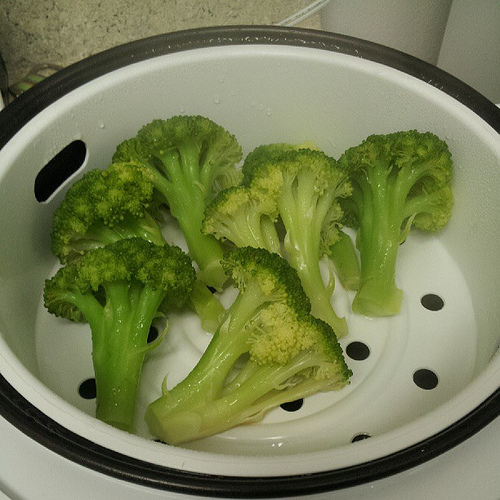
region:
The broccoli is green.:
[332, 120, 455, 326]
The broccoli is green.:
[244, 143, 358, 275]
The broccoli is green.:
[195, 173, 290, 260]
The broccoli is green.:
[106, 108, 251, 254]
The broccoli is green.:
[43, 160, 176, 270]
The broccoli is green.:
[38, 228, 200, 438]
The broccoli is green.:
[146, 234, 358, 469]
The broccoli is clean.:
[146, 235, 359, 458]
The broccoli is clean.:
[36, 225, 199, 432]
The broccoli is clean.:
[331, 113, 461, 334]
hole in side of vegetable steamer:
[36, 125, 90, 208]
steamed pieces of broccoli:
[60, 118, 447, 440]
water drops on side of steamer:
[74, 98, 109, 140]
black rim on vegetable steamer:
[15, 408, 97, 480]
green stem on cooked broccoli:
[350, 209, 407, 317]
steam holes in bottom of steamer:
[335, 277, 471, 407]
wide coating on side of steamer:
[240, 66, 352, 138]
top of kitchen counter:
[7, 0, 92, 45]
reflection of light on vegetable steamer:
[259, 427, 292, 454]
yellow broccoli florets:
[246, 159, 293, 219]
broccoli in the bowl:
[357, 142, 431, 320]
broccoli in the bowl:
[219, 303, 298, 411]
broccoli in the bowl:
[55, 260, 151, 399]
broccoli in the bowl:
[45, 168, 153, 227]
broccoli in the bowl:
[152, 103, 215, 194]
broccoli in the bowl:
[189, 183, 281, 235]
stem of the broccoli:
[136, 380, 198, 444]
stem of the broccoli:
[96, 384, 150, 421]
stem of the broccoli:
[362, 269, 399, 320]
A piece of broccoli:
[47, 237, 204, 417]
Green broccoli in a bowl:
[49, 235, 195, 422]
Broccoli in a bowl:
[15, 35, 482, 472]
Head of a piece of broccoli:
[46, 239, 206, 326]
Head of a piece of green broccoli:
[54, 241, 195, 331]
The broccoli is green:
[35, 60, 436, 463]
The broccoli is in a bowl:
[33, 55, 461, 478]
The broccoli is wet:
[49, 28, 428, 480]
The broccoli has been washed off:
[40, 55, 449, 462]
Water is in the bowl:
[78, 84, 130, 131]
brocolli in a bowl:
[29, 22, 464, 469]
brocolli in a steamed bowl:
[84, 131, 405, 486]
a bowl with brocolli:
[72, 138, 499, 493]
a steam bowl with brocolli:
[50, 125, 437, 488]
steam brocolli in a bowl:
[85, 90, 498, 495]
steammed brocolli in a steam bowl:
[75, 100, 497, 416]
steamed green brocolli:
[36, 110, 468, 496]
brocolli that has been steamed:
[77, 110, 485, 411]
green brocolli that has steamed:
[86, 103, 497, 401]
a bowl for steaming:
[51, 74, 411, 474]